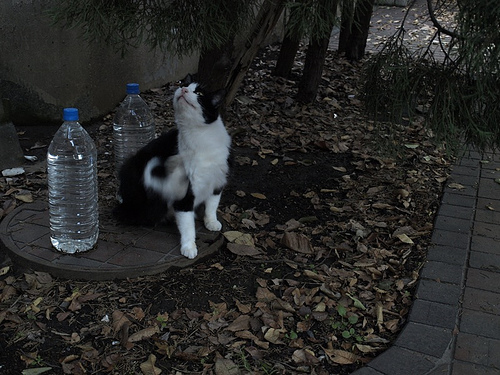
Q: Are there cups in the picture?
A: No, there are no cups.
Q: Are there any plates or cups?
A: No, there are no cups or plates.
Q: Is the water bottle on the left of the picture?
A: Yes, the water bottle is on the left of the image.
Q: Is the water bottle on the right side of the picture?
A: No, the water bottle is on the left of the image.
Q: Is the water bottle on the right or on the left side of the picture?
A: The water bottle is on the left of the image.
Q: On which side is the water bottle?
A: The water bottle is on the left of the image.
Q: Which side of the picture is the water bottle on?
A: The water bottle is on the left of the image.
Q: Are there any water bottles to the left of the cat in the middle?
A: Yes, there is a water bottle to the left of the cat.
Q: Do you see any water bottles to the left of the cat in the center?
A: Yes, there is a water bottle to the left of the cat.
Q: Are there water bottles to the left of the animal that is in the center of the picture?
A: Yes, there is a water bottle to the left of the cat.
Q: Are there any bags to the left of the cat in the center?
A: No, there is a water bottle to the left of the cat.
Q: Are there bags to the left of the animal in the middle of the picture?
A: No, there is a water bottle to the left of the cat.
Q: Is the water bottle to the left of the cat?
A: Yes, the water bottle is to the left of the cat.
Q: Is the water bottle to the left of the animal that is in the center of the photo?
A: Yes, the water bottle is to the left of the cat.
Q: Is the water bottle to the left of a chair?
A: No, the water bottle is to the left of the cat.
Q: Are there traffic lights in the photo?
A: No, there are no traffic lights.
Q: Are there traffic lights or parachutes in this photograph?
A: No, there are no traffic lights or parachutes.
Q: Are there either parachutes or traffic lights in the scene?
A: No, there are no traffic lights or parachutes.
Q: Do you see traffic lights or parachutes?
A: No, there are no traffic lights or parachutes.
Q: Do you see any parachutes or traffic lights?
A: No, there are no traffic lights or parachutes.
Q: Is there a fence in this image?
A: No, there are no fences.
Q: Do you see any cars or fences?
A: No, there are no fences or cars.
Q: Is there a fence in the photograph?
A: No, there are no fences.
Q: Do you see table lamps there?
A: No, there are no table lamps.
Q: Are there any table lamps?
A: No, there are no table lamps.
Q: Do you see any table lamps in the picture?
A: No, there are no table lamps.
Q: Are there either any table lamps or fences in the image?
A: No, there are no table lamps or fences.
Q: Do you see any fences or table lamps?
A: No, there are no table lamps or fences.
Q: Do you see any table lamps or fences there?
A: No, there are no table lamps or fences.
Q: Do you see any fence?
A: No, there are no fences.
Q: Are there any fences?
A: No, there are no fences.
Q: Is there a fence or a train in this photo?
A: No, there are no fences or trains.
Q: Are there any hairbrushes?
A: No, there are no hairbrushes.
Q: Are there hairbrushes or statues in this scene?
A: No, there are no hairbrushes or statues.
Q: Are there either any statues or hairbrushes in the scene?
A: No, there are no hairbrushes or statues.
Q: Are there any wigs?
A: No, there are no wigs.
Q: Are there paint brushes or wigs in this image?
A: No, there are no wigs or paint brushes.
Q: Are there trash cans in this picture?
A: No, there are no trash cans.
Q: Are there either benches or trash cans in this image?
A: No, there are no trash cans or benches.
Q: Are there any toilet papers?
A: No, there are no toilet papers.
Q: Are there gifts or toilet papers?
A: No, there are no toilet papers or gifts.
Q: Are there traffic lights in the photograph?
A: No, there are no traffic lights.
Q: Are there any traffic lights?
A: No, there are no traffic lights.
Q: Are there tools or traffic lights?
A: No, there are no traffic lights or tools.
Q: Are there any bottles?
A: Yes, there is a bottle.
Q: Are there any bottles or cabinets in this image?
A: Yes, there is a bottle.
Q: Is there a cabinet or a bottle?
A: Yes, there is a bottle.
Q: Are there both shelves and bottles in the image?
A: No, there is a bottle but no shelves.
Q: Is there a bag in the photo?
A: No, there are no bags.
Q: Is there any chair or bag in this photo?
A: No, there are no bags or chairs.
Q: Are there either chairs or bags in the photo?
A: No, there are no bags or chairs.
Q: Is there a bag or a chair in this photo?
A: No, there are no bags or chairs.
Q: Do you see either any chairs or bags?
A: No, there are no bags or chairs.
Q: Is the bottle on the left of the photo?
A: Yes, the bottle is on the left of the image.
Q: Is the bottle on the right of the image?
A: No, the bottle is on the left of the image.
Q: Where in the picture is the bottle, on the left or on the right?
A: The bottle is on the left of the image.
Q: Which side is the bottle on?
A: The bottle is on the left of the image.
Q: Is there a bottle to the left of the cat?
A: Yes, there is a bottle to the left of the cat.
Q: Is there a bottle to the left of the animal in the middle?
A: Yes, there is a bottle to the left of the cat.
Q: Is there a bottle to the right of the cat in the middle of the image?
A: No, the bottle is to the left of the cat.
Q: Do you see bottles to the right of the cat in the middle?
A: No, the bottle is to the left of the cat.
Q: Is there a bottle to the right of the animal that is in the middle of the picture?
A: No, the bottle is to the left of the cat.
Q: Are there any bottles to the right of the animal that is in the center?
A: No, the bottle is to the left of the cat.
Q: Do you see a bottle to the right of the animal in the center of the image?
A: No, the bottle is to the left of the cat.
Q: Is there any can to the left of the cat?
A: No, there is a bottle to the left of the cat.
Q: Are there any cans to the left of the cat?
A: No, there is a bottle to the left of the cat.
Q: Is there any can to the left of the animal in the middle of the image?
A: No, there is a bottle to the left of the cat.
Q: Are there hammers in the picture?
A: No, there are no hammers.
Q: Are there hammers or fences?
A: No, there are no hammers or fences.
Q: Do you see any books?
A: No, there are no books.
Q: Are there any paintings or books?
A: No, there are no books or paintings.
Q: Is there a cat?
A: Yes, there is a cat.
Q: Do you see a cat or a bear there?
A: Yes, there is a cat.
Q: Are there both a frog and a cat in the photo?
A: No, there is a cat but no frogs.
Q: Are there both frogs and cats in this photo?
A: No, there is a cat but no frogs.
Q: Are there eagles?
A: No, there are no eagles.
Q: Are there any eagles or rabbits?
A: No, there are no eagles or rabbits.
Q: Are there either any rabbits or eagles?
A: No, there are no eagles or rabbits.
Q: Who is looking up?
A: The cat is looking up.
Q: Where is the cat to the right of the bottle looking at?
A: The cat is looking up.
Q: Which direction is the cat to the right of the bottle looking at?
A: The cat is looking up.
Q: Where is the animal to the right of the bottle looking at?
A: The cat is looking up.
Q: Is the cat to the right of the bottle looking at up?
A: Yes, the cat is looking up.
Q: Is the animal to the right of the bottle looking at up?
A: Yes, the cat is looking up.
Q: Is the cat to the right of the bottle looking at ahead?
A: No, the cat is looking up.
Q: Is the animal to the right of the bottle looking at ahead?
A: No, the cat is looking up.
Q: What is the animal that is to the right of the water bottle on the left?
A: The animal is a cat.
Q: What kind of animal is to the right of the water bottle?
A: The animal is a cat.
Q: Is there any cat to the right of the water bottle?
A: Yes, there is a cat to the right of the water bottle.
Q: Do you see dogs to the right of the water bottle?
A: No, there is a cat to the right of the water bottle.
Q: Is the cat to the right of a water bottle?
A: Yes, the cat is to the right of a water bottle.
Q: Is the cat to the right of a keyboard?
A: No, the cat is to the right of a water bottle.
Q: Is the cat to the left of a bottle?
A: No, the cat is to the right of a bottle.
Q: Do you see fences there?
A: No, there are no fences.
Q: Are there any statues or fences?
A: No, there are no fences or statues.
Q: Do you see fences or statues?
A: No, there are no fences or statues.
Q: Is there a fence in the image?
A: No, there are no fences.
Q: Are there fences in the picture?
A: No, there are no fences.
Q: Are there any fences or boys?
A: No, there are no fences or boys.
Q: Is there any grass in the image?
A: Yes, there is grass.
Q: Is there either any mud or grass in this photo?
A: Yes, there is grass.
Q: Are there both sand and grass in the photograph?
A: No, there is grass but no sand.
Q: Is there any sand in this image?
A: No, there is no sand.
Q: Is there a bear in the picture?
A: No, there are no bears.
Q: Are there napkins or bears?
A: No, there are no bears or napkins.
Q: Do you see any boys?
A: No, there are no boys.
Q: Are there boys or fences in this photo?
A: No, there are no boys or fences.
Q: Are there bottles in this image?
A: Yes, there is a bottle.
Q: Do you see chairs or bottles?
A: Yes, there is a bottle.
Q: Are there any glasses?
A: No, there are no glasses.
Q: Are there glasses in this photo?
A: No, there are no glasses.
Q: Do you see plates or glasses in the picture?
A: No, there are no glasses or plates.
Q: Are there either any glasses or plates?
A: No, there are no glasses or plates.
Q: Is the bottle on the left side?
A: Yes, the bottle is on the left of the image.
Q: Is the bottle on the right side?
A: No, the bottle is on the left of the image.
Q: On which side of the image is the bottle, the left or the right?
A: The bottle is on the left of the image.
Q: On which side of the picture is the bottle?
A: The bottle is on the left of the image.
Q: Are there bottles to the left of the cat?
A: Yes, there is a bottle to the left of the cat.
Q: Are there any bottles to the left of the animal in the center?
A: Yes, there is a bottle to the left of the cat.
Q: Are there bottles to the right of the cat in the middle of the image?
A: No, the bottle is to the left of the cat.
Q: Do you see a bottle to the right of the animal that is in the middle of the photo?
A: No, the bottle is to the left of the cat.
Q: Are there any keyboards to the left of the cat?
A: No, there is a bottle to the left of the cat.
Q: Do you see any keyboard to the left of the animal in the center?
A: No, there is a bottle to the left of the cat.